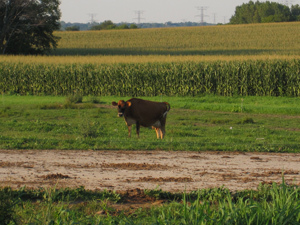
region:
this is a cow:
[115, 94, 175, 133]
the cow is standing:
[114, 93, 173, 138]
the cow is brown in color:
[141, 103, 156, 117]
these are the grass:
[205, 197, 243, 224]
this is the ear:
[126, 99, 132, 105]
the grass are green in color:
[213, 197, 259, 221]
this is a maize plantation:
[208, 59, 259, 89]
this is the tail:
[161, 105, 170, 114]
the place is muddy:
[130, 153, 189, 183]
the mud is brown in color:
[141, 150, 185, 187]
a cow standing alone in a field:
[109, 95, 170, 143]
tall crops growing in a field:
[0, 50, 299, 98]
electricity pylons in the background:
[84, 5, 210, 26]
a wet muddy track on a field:
[2, 146, 299, 203]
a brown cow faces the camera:
[110, 93, 173, 143]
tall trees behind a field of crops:
[214, 0, 299, 26]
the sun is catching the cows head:
[108, 96, 135, 121]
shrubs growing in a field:
[35, 88, 107, 112]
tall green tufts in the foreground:
[42, 170, 296, 223]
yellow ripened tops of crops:
[1, 51, 298, 71]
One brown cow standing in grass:
[110, 97, 170, 140]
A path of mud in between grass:
[0, 140, 297, 203]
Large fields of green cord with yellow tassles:
[0, 20, 299, 98]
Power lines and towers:
[83, 4, 234, 29]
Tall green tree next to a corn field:
[2, 0, 61, 98]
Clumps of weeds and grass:
[26, 88, 105, 110]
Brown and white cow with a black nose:
[109, 97, 169, 139]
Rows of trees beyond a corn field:
[54, 0, 297, 35]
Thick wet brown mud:
[0, 146, 299, 197]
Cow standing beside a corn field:
[110, 56, 169, 139]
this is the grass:
[5, 97, 36, 127]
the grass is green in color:
[36, 115, 87, 139]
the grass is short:
[40, 114, 99, 147]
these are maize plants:
[152, 29, 290, 92]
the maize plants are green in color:
[184, 33, 257, 91]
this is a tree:
[1, 0, 60, 49]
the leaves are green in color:
[30, 3, 55, 31]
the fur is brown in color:
[137, 103, 154, 118]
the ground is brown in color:
[91, 158, 159, 185]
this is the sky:
[102, 3, 129, 14]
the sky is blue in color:
[108, 4, 126, 14]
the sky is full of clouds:
[96, 5, 124, 15]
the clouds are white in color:
[105, 3, 119, 15]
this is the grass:
[184, 99, 233, 111]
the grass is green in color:
[190, 127, 208, 143]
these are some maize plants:
[207, 26, 288, 96]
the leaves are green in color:
[34, 7, 46, 12]